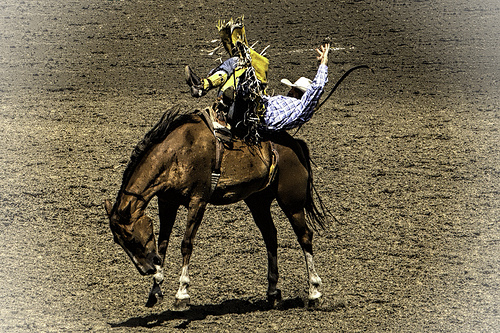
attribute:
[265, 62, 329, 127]
shirt — checkered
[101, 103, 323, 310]
horse — brown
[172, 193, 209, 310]
leg — white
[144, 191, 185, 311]
leg — white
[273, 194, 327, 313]
leg — white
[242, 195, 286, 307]
leg — white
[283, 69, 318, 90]
hat — cowboy style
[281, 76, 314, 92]
hat — cowboy style, white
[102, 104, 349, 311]
horse — brown